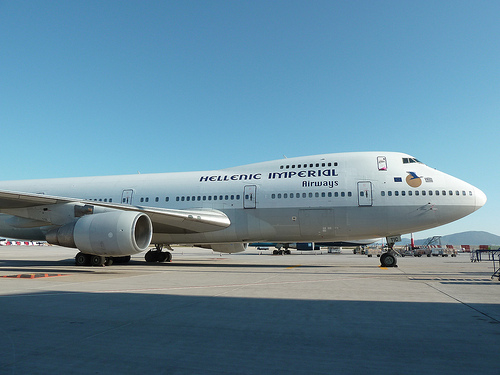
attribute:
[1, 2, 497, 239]
sky — blue